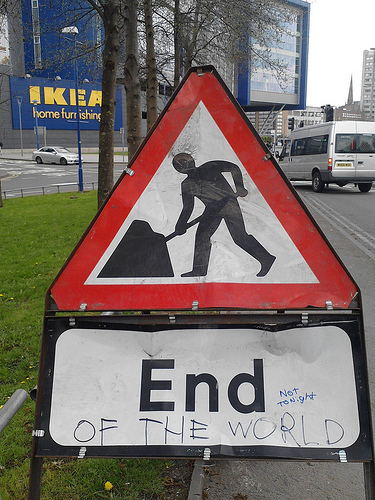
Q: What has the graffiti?
A: A sign.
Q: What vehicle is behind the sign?
A: A van.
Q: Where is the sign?
A: On the side of a street.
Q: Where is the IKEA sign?
A: On the building.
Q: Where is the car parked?
A: Near the IKEA building.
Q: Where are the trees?
A: Behind the signs.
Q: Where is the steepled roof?
A: In the distance.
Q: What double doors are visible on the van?
A: The back doors.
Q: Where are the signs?
A: In the grass area.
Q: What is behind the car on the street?
A: Light poles.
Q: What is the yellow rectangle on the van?
A: The license plate.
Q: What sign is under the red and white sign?
A: The black and white sign.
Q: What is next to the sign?
A: A pipe.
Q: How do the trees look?
A: No leaves.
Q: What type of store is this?
A: Home furnishing store.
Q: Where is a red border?
A: On top street sign.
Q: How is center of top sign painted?
A: White.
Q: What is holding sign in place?
A: Silver clips.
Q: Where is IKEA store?
A: On left of road.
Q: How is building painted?
A: Blue and grey.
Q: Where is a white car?
A: In front of IKEA store.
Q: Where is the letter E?
A: On the sign.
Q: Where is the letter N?
A: On the sign.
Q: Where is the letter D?
A: On the sign.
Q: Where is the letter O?
A: On the sign.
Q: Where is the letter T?
A: On the sign.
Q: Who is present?
A: No one.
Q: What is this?
A: Sign.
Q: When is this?
A: Daytime.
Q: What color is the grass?
A: Green.